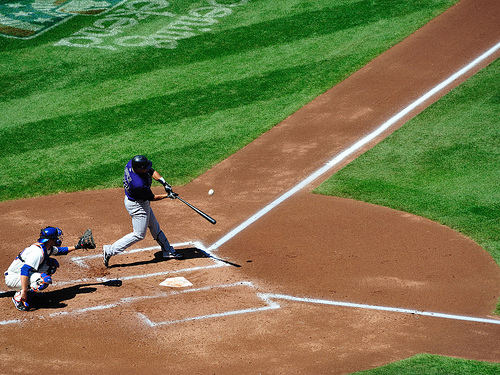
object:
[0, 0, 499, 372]
dirt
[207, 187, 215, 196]
ball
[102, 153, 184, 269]
batter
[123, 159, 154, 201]
jersey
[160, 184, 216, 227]
bat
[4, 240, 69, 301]
uniform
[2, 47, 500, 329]
lines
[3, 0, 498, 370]
baseball field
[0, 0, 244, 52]
design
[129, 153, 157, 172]
helmet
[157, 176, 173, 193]
gloves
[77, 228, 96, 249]
catcher mitt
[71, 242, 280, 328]
chalk lines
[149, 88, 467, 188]
green grass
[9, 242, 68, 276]
shirt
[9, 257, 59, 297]
pants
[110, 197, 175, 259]
pants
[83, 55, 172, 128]
grass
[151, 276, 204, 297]
surface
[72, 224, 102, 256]
mit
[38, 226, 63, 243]
helmet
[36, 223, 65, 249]
head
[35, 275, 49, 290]
pads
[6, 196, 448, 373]
mound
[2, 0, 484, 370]
field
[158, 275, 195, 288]
diamond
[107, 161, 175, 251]
uniform